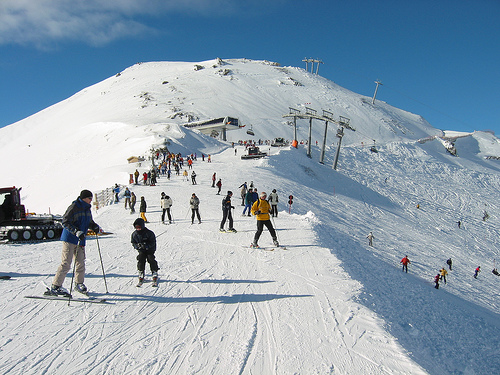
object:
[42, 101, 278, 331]
snow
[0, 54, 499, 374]
mountain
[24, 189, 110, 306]
skier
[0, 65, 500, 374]
ski slope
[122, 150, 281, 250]
skiers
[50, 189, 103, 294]
man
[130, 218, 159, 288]
kid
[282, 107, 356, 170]
poles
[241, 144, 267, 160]
snow machine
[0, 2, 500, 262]
background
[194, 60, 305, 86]
rocks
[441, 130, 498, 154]
hill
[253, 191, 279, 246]
person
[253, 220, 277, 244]
pants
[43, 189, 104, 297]
person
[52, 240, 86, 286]
pants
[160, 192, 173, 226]
person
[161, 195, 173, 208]
jacket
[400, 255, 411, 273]
person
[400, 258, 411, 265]
jacket